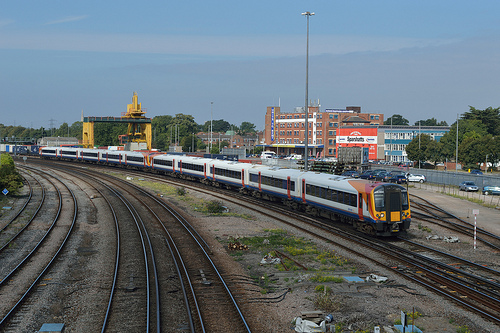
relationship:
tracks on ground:
[7, 162, 219, 327] [56, 177, 496, 310]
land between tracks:
[208, 192, 387, 332] [7, 162, 219, 327]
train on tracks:
[25, 147, 414, 258] [7, 162, 219, 327]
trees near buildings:
[403, 123, 498, 196] [231, 105, 417, 170]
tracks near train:
[7, 162, 219, 327] [25, 147, 414, 258]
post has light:
[297, 8, 318, 175] [297, 14, 317, 23]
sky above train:
[18, 6, 222, 105] [25, 147, 414, 258]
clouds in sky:
[116, 31, 372, 60] [18, 6, 222, 105]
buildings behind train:
[231, 105, 417, 170] [25, 147, 414, 258]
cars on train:
[50, 125, 298, 211] [25, 147, 414, 258]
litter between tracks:
[230, 217, 391, 290] [7, 162, 219, 327]